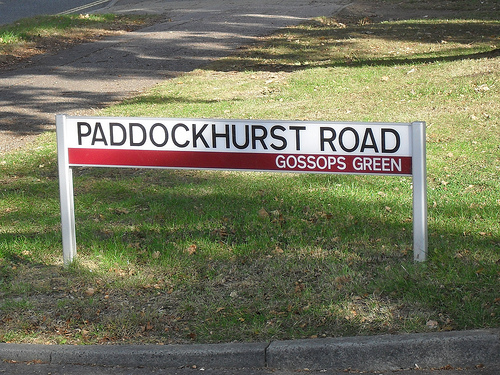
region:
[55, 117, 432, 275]
this is a sign post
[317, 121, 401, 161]
the writing is in black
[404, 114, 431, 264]
the pole is short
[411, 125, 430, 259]
the pole is thin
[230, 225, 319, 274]
these are the grass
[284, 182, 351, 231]
the grass are green in color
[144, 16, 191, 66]
this is the road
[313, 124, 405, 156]
it is written road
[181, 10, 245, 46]
the road is tarmacked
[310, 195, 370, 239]
the grass are short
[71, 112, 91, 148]
black letter P on sign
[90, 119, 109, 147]
black letter A on sign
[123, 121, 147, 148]
black letter D on sign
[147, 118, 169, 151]
black letter O on sign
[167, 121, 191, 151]
black letter C on sign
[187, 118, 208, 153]
black letter K on sign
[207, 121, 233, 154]
black letter H on sign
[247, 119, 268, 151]
black letter R on sign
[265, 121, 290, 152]
black letter S on sign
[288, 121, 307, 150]
black letter T on sign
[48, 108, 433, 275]
red black and white street name sign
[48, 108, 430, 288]
street is called paddockhurst road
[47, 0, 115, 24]
double yellow lines on a road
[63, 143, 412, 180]
red bar on a street sign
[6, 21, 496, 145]
shadows of trees on the ground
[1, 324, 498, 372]
concrete kerb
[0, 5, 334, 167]
concrete foot path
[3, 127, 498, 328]
green grass under a street sign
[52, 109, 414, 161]
street name in black print on a white background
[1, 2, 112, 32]
small section of a road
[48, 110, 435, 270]
a sign in the grass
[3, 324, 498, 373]
a curb along the grass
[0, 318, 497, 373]
a curb is grey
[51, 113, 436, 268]
the sign is white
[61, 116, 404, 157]
these letters are black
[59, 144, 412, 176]
this strip is red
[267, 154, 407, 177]
these letters are white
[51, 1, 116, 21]
lines on the road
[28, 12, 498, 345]
leaves on the grass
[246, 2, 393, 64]
dirt beside the road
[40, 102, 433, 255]
The sign is long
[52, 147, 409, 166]
Half of the sign is red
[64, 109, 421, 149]
half of the sign is white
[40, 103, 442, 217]
The sign is white and red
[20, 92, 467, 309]
The sign is on the grass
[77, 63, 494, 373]
the sign is next to a street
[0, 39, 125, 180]
the sign is near a sidewalk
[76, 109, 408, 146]
the top text is black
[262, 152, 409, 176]
the bottom text is white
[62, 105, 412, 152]
the sign says Paddockhurst road